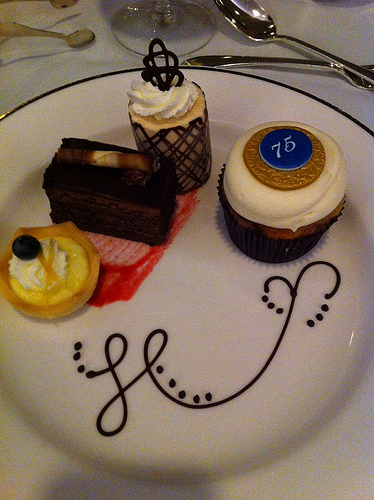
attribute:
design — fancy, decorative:
[72, 260, 342, 437]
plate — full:
[1, 64, 374, 499]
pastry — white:
[125, 40, 211, 196]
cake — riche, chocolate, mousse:
[43, 139, 176, 246]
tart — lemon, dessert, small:
[1, 219, 102, 322]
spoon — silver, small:
[212, 1, 373, 80]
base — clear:
[111, 2, 217, 55]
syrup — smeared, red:
[89, 246, 165, 308]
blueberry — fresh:
[10, 232, 38, 260]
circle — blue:
[260, 126, 313, 171]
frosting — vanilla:
[221, 121, 349, 231]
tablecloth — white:
[2, 1, 145, 115]